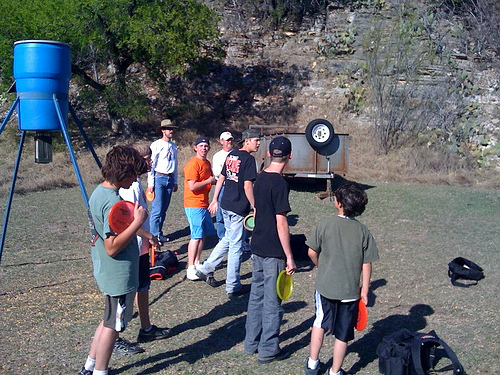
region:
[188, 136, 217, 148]
The man is wearing a hat.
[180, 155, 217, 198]
The man has an orange shirt on.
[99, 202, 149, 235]
The woman is holding a red Frisbee.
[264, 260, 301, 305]
The man is holding a yellow Frisbee.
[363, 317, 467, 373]
There is a bag on the ground.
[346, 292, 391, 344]
The boy is holding an orange Frisbee.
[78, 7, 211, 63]
The tree is green.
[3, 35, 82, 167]
The large object is blue.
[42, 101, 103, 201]
The legs are blue.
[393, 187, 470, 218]
The grass is green.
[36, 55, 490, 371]
Group of people getting ready to play frisbee.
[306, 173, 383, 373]
Young boy on right holding an orange frisbee.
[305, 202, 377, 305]
Short sleeve grey tee shirt.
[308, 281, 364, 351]
Pair of dark shorts with white stripe.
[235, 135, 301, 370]
Boy holding a yellow frisbee.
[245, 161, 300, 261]
A short sleeve tee shirt.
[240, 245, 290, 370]
Boy on right has on a pair of blue jeans.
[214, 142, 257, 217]
Short sleeve tee shirt with graphics.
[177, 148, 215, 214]
An orange short sleeve tee shirt.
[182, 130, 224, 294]
Boy in orange shirt wearing hat turned backwards.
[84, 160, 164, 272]
boy holding a red frisbee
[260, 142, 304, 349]
boy holding a yellow frisbee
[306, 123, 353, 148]
tire on the front of a trailer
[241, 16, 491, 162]
side of hill or mountain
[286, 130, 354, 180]
rust on the trailer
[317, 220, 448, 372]
shadow of the smaller boy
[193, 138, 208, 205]
guy wearing an orange shirt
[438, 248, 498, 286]
black bag laying on the ground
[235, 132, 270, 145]
wearing his ball cap backwards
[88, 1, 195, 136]
tree on the side of group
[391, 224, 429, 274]
part of some grass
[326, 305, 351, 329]
part of a black short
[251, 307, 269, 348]
part of a trouser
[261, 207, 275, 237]
part of a dark top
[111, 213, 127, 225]
part of a red dish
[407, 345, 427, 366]
handle of a bag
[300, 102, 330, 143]
part part of a wheel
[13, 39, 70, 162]
blue tank on stand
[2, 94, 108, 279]
blue, metal arms of stand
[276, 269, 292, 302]
yellow frisbee in man's hand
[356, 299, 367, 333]
orange frisbee in boy's hand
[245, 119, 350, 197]
rusty metal trailer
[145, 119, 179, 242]
man in cowboy hat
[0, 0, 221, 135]
green tree behind group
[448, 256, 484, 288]
black bag on ground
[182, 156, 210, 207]
bright orange shirt on boy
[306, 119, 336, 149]
tire on rusty trailer